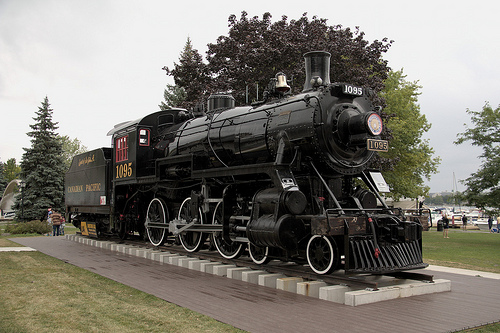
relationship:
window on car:
[137, 127, 149, 148] [67, 51, 428, 276]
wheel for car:
[306, 234, 337, 275] [67, 51, 428, 276]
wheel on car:
[305, 230, 338, 277] [67, 51, 428, 276]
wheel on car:
[244, 227, 275, 267] [67, 51, 428, 276]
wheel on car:
[213, 200, 248, 259] [67, 51, 428, 276]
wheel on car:
[178, 197, 206, 253] [67, 51, 428, 276]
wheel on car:
[141, 191, 173, 244] [67, 51, 428, 276]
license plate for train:
[367, 139, 389, 152] [198, 72, 413, 254]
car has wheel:
[67, 51, 428, 276] [303, 226, 343, 278]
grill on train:
[345, 229, 427, 277] [66, 76, 420, 277]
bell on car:
[267, 70, 294, 96] [67, 51, 428, 276]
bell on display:
[267, 70, 294, 96] [66, 230, 456, 305]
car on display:
[67, 51, 428, 276] [66, 230, 456, 305]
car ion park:
[67, 51, 428, 276] [0, 0, 496, 330]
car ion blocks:
[67, 51, 428, 276] [47, 226, 464, 312]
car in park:
[67, 51, 428, 276] [427, 200, 498, 268]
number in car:
[343, 82, 364, 94] [67, 51, 428, 276]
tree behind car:
[15, 90, 71, 223] [67, 151, 109, 234]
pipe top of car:
[303, 51, 331, 92] [67, 51, 428, 276]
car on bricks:
[67, 51, 428, 276] [323, 284, 455, 309]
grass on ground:
[0, 261, 168, 331] [8, 230, 498, 330]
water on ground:
[209, 273, 264, 308] [8, 230, 498, 330]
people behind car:
[43, 207, 72, 236] [67, 51, 428, 276]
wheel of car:
[145, 198, 167, 247] [67, 51, 428, 276]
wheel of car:
[178, 197, 206, 253] [67, 51, 428, 276]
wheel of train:
[213, 200, 248, 259] [65, 104, 439, 283]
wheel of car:
[306, 234, 337, 275] [67, 51, 428, 276]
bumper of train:
[334, 210, 434, 280] [39, 43, 436, 284]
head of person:
[52, 205, 58, 213] [38, 206, 59, 239]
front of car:
[307, 53, 430, 275] [67, 51, 428, 276]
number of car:
[112, 161, 132, 177] [67, 51, 428, 276]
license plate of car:
[365, 138, 389, 152] [67, 51, 428, 276]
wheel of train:
[306, 234, 337, 275] [39, 43, 436, 284]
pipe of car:
[296, 42, 336, 93] [67, 51, 428, 276]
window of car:
[114, 135, 128, 161] [67, 51, 428, 276]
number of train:
[345, 85, 363, 95] [101, 76, 446, 307]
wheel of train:
[210, 208, 248, 275] [87, 93, 469, 300]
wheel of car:
[173, 196, 208, 254] [67, 51, 428, 276]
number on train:
[116, 162, 132, 179] [87, 93, 469, 300]